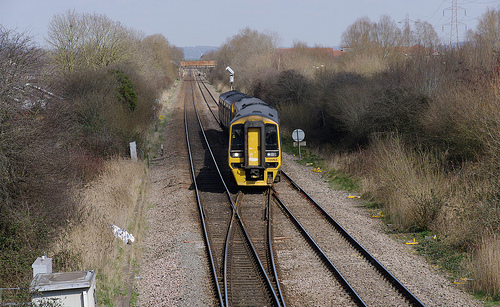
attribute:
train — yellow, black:
[209, 82, 291, 199]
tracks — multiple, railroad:
[195, 187, 417, 305]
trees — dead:
[11, 26, 182, 192]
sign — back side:
[289, 126, 310, 162]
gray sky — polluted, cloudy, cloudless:
[1, 4, 481, 44]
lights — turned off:
[228, 147, 279, 160]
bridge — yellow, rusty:
[176, 57, 217, 70]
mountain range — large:
[163, 41, 224, 60]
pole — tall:
[443, 3, 466, 45]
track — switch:
[198, 188, 320, 306]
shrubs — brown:
[330, 128, 489, 221]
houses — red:
[257, 39, 457, 64]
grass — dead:
[338, 138, 499, 268]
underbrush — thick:
[36, 75, 165, 238]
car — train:
[224, 103, 284, 188]